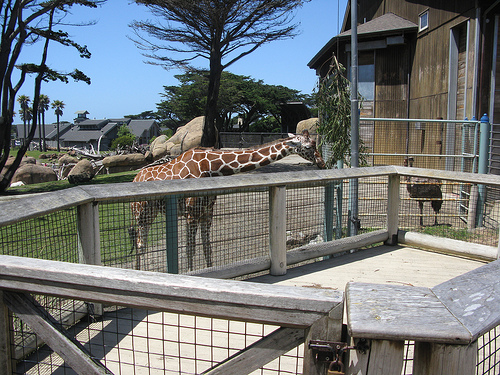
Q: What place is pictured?
A: It is a pen.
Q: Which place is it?
A: It is a pen.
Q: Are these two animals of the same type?
A: No, they are giraffes and birds.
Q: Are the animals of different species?
A: Yes, they are giraffes and birds.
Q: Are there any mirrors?
A: No, there are no mirrors.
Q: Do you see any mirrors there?
A: No, there are no mirrors.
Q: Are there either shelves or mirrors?
A: No, there are no mirrors or shelves.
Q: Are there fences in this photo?
A: Yes, there is a fence.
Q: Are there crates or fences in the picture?
A: Yes, there is a fence.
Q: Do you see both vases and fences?
A: No, there is a fence but no vases.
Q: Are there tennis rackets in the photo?
A: No, there are no tennis rackets.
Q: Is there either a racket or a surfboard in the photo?
A: No, there are no rackets or surfboards.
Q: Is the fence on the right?
A: Yes, the fence is on the right of the image.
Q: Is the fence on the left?
A: No, the fence is on the right of the image.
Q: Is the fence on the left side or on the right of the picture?
A: The fence is on the right of the image.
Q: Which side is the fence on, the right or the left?
A: The fence is on the right of the image.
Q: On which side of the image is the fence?
A: The fence is on the right of the image.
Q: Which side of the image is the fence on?
A: The fence is on the right of the image.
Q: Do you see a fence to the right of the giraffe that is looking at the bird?
A: Yes, there is a fence to the right of the giraffe.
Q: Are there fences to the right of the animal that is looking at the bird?
A: Yes, there is a fence to the right of the giraffe.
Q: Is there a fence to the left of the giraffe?
A: No, the fence is to the right of the giraffe.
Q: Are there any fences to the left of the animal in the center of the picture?
A: No, the fence is to the right of the giraffe.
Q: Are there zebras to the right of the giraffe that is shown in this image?
A: No, there is a fence to the right of the giraffe.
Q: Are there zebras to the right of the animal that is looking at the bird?
A: No, there is a fence to the right of the giraffe.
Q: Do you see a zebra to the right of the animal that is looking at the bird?
A: No, there is a fence to the right of the giraffe.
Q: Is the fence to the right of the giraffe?
A: Yes, the fence is to the right of the giraffe.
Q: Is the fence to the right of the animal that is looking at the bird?
A: Yes, the fence is to the right of the giraffe.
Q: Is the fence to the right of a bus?
A: No, the fence is to the right of the giraffe.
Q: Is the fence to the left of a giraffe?
A: No, the fence is to the right of a giraffe.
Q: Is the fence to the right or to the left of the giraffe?
A: The fence is to the right of the giraffe.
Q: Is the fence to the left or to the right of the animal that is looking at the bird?
A: The fence is to the right of the giraffe.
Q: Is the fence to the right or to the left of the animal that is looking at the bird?
A: The fence is to the right of the giraffe.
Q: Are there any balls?
A: No, there are no balls.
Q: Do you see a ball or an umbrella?
A: No, there are no balls or umbrellas.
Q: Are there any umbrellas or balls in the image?
A: No, there are no balls or umbrellas.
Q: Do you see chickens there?
A: No, there are no chickens.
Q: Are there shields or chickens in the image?
A: No, there are no chickens or shields.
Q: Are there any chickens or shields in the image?
A: No, there are no chickens or shields.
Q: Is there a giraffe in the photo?
A: Yes, there is a giraffe.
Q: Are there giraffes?
A: Yes, there is a giraffe.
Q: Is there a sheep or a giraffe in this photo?
A: Yes, there is a giraffe.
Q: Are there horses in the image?
A: No, there are no horses.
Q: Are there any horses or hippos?
A: No, there are no horses or hippos.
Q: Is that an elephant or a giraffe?
A: That is a giraffe.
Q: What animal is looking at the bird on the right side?
A: The giraffe is looking at the bird.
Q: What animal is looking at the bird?
A: The giraffe is looking at the bird.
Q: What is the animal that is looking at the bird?
A: The animal is a giraffe.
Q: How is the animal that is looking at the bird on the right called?
A: The animal is a giraffe.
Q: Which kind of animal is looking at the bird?
A: The animal is a giraffe.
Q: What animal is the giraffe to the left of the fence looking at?
A: The giraffe is looking at the bird.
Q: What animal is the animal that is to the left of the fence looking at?
A: The giraffe is looking at the bird.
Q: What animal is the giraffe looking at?
A: The giraffe is looking at the bird.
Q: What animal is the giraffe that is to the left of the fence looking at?
A: The giraffe is looking at the bird.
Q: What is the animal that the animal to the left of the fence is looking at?
A: The animal is a bird.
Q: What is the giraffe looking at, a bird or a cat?
A: The giraffe is looking at a bird.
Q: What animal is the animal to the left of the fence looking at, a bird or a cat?
A: The giraffe is looking at a bird.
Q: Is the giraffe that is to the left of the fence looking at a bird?
A: Yes, the giraffe is looking at a bird.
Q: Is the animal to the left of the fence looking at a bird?
A: Yes, the giraffe is looking at a bird.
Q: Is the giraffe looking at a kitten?
A: No, the giraffe is looking at a bird.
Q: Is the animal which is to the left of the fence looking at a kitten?
A: No, the giraffe is looking at a bird.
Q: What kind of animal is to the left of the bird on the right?
A: The animal is a giraffe.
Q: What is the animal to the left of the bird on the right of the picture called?
A: The animal is a giraffe.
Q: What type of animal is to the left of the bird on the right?
A: The animal is a giraffe.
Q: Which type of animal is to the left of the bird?
A: The animal is a giraffe.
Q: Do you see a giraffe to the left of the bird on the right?
A: Yes, there is a giraffe to the left of the bird.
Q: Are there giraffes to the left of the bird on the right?
A: Yes, there is a giraffe to the left of the bird.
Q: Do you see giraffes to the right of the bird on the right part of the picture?
A: No, the giraffe is to the left of the bird.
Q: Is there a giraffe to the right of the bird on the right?
A: No, the giraffe is to the left of the bird.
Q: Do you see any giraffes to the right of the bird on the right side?
A: No, the giraffe is to the left of the bird.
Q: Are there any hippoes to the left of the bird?
A: No, there is a giraffe to the left of the bird.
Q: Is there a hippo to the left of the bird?
A: No, there is a giraffe to the left of the bird.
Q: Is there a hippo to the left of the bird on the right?
A: No, there is a giraffe to the left of the bird.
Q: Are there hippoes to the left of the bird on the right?
A: No, there is a giraffe to the left of the bird.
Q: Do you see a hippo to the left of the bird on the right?
A: No, there is a giraffe to the left of the bird.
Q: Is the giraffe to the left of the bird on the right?
A: Yes, the giraffe is to the left of the bird.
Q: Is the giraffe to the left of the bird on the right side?
A: Yes, the giraffe is to the left of the bird.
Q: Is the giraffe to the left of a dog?
A: No, the giraffe is to the left of the bird.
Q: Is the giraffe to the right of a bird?
A: No, the giraffe is to the left of a bird.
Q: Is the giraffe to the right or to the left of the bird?
A: The giraffe is to the left of the bird.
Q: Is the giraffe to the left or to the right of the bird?
A: The giraffe is to the left of the bird.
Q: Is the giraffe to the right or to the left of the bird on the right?
A: The giraffe is to the left of the bird.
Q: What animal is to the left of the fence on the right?
A: The animal is a giraffe.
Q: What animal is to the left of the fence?
A: The animal is a giraffe.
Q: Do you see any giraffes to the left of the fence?
A: Yes, there is a giraffe to the left of the fence.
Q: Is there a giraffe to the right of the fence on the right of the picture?
A: No, the giraffe is to the left of the fence.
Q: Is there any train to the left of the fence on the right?
A: No, there is a giraffe to the left of the fence.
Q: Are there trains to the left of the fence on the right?
A: No, there is a giraffe to the left of the fence.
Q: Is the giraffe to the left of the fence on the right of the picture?
A: Yes, the giraffe is to the left of the fence.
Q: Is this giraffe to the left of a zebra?
A: No, the giraffe is to the left of the fence.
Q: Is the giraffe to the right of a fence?
A: No, the giraffe is to the left of a fence.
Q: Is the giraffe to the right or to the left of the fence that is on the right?
A: The giraffe is to the left of the fence.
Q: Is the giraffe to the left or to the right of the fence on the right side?
A: The giraffe is to the left of the fence.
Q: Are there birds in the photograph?
A: Yes, there is a bird.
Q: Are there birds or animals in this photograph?
A: Yes, there is a bird.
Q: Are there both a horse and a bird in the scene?
A: No, there is a bird but no horses.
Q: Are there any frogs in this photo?
A: No, there are no frogs.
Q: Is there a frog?
A: No, there are no frogs.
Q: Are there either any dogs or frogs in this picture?
A: No, there are no frogs or dogs.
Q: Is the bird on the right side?
A: Yes, the bird is on the right of the image.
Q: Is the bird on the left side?
A: No, the bird is on the right of the image.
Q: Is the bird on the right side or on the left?
A: The bird is on the right of the image.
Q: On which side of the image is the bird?
A: The bird is on the right of the image.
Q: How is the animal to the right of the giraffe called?
A: The animal is a bird.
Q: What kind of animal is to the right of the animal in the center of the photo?
A: The animal is a bird.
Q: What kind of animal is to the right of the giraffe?
A: The animal is a bird.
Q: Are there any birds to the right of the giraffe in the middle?
A: Yes, there is a bird to the right of the giraffe.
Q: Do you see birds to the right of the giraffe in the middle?
A: Yes, there is a bird to the right of the giraffe.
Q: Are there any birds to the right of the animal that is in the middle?
A: Yes, there is a bird to the right of the giraffe.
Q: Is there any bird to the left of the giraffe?
A: No, the bird is to the right of the giraffe.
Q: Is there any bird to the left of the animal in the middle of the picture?
A: No, the bird is to the right of the giraffe.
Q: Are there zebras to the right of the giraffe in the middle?
A: No, there is a bird to the right of the giraffe.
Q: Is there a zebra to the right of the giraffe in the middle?
A: No, there is a bird to the right of the giraffe.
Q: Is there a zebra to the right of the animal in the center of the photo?
A: No, there is a bird to the right of the giraffe.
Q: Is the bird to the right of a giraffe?
A: Yes, the bird is to the right of a giraffe.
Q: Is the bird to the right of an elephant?
A: No, the bird is to the right of a giraffe.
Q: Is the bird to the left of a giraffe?
A: No, the bird is to the right of a giraffe.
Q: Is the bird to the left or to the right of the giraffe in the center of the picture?
A: The bird is to the right of the giraffe.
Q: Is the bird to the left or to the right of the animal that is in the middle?
A: The bird is to the right of the giraffe.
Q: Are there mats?
A: No, there are no mats.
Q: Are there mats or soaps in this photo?
A: No, there are no mats or soaps.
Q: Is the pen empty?
A: Yes, the pen is empty.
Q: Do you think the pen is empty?
A: Yes, the pen is empty.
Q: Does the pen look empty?
A: Yes, the pen is empty.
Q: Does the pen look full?
A: No, the pen is empty.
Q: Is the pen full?
A: No, the pen is empty.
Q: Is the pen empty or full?
A: The pen is empty.